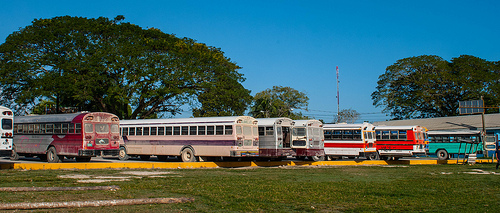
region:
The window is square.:
[126, 123, 136, 136]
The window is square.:
[133, 123, 143, 136]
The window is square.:
[148, 123, 158, 136]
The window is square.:
[156, 124, 166, 136]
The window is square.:
[163, 123, 173, 135]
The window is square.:
[171, 123, 182, 136]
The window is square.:
[188, 123, 198, 135]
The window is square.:
[197, 124, 208, 136]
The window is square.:
[213, 121, 224, 136]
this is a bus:
[126, 110, 264, 159]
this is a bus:
[258, 122, 300, 154]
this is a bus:
[294, 120, 330, 164]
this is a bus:
[323, 116, 380, 162]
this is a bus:
[376, 119, 431, 167]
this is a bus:
[428, 113, 493, 167]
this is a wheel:
[45, 141, 62, 168]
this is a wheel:
[178, 135, 206, 173]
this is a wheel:
[433, 144, 456, 167]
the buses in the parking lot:
[0, 107, 432, 165]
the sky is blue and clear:
[190, 4, 498, 49]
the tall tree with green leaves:
[6, 14, 267, 117]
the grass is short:
[45, 165, 498, 208]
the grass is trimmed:
[35, 160, 496, 205]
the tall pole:
[327, 52, 345, 127]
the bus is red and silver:
[19, 116, 123, 157]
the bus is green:
[420, 128, 488, 155]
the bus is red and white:
[325, 123, 374, 155]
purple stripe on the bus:
[126, 105, 245, 171]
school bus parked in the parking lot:
[10, 107, 123, 158]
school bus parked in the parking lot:
[113, 117, 258, 160]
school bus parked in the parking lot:
[252, 116, 297, 158]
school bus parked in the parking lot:
[321, 120, 376, 157]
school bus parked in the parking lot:
[371, 121, 428, 161]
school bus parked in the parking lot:
[422, 127, 483, 162]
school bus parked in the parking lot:
[0, 104, 15, 159]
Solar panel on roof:
[454, 94, 486, 118]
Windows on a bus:
[129, 125, 160, 134]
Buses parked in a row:
[143, 112, 480, 167]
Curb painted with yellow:
[63, 162, 210, 169]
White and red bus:
[325, 120, 373, 159]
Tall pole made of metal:
[331, 63, 348, 125]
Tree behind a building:
[377, 52, 496, 108]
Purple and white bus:
[132, 116, 259, 166]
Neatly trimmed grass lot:
[358, 167, 465, 211]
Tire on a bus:
[431, 147, 450, 163]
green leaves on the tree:
[200, 65, 230, 89]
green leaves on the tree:
[402, 71, 414, 88]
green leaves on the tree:
[405, 69, 429, 85]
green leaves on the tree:
[434, 69, 449, 89]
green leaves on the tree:
[460, 73, 476, 88]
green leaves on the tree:
[213, 76, 230, 96]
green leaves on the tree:
[177, 38, 202, 62]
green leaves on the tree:
[129, 77, 149, 92]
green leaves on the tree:
[108, 33, 139, 61]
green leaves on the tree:
[102, 83, 129, 110]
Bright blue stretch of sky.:
[1, 1, 499, 118]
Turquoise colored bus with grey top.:
[425, 128, 485, 161]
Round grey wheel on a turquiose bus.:
[435, 149, 448, 161]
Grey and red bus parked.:
[11, 111, 121, 161]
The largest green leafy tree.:
[1, 15, 256, 119]